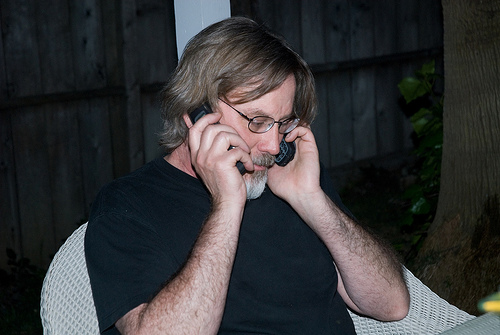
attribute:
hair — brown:
[146, 13, 323, 153]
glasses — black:
[222, 90, 314, 142]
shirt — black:
[73, 140, 363, 333]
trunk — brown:
[423, 14, 483, 270]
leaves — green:
[397, 58, 433, 178]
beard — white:
[232, 143, 282, 205]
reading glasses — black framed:
[213, 90, 303, 141]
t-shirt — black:
[72, 160, 357, 330]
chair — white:
[30, 190, 474, 331]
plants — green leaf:
[324, 49, 449, 260]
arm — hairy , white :
[264, 148, 439, 328]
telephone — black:
[194, 108, 209, 115]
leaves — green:
[398, 64, 420, 134]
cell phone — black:
[194, 110, 204, 119]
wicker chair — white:
[47, 277, 82, 317]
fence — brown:
[51, 44, 126, 142]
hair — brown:
[385, 249, 395, 265]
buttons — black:
[280, 149, 290, 156]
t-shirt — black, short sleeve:
[262, 254, 325, 317]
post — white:
[172, 0, 233, 63]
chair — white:
[38, 218, 479, 333]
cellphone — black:
[277, 136, 294, 168]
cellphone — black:
[276, 129, 299, 163]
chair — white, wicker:
[48, 229, 101, 330]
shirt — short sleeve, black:
[222, 190, 349, 330]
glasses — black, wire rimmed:
[219, 98, 299, 133]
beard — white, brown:
[238, 167, 269, 197]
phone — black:
[189, 94, 211, 119]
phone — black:
[272, 137, 294, 171]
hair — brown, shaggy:
[154, 10, 289, 150]